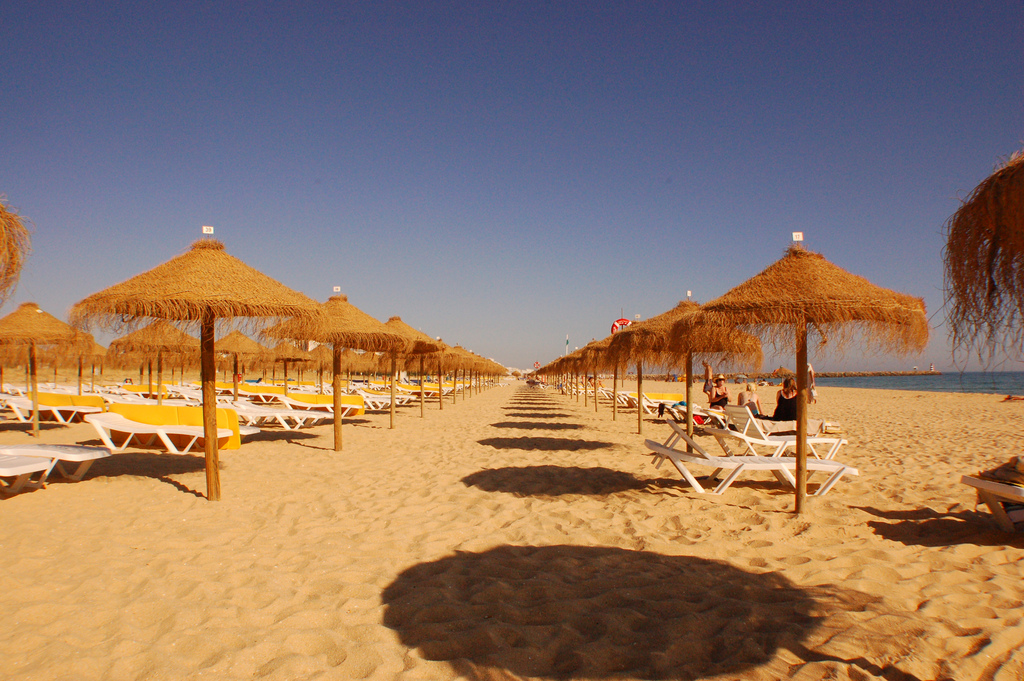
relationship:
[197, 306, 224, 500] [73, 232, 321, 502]
pole in umbrella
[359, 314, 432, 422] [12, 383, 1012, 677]
umbrella on beach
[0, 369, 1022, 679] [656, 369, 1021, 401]
beach near water